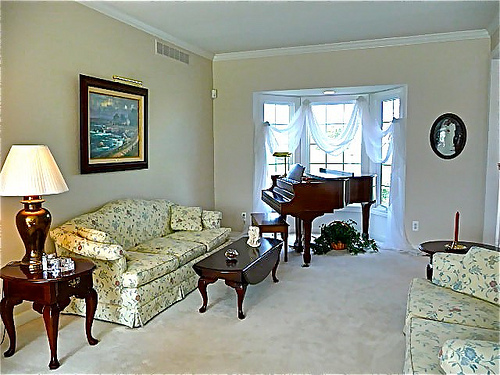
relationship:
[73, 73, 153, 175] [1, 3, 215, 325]
picture on wall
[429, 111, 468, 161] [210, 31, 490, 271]
picture on wall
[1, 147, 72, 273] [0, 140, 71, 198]
lamp has white shade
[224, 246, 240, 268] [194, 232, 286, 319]
candle on top of table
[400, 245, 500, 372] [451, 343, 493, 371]
couch has floral print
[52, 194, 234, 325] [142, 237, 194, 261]
couch has floral print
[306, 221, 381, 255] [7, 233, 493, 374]
plant on floor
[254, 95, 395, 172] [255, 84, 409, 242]
curtains on window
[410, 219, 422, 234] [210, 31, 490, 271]
electric plug on wall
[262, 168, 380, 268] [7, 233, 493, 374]
piano on floor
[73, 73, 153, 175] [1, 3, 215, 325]
painting on wall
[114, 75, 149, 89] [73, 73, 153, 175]
light above painting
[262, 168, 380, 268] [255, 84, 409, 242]
piano in front of window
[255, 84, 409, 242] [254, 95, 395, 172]
window has white curtains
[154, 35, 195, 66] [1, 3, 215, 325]
vent on wall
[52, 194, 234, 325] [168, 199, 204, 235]
couch has pillow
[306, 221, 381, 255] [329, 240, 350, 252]
plant in basket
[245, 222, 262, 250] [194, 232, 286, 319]
decoration on coffee table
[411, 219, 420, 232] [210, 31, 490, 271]
electric plug on wall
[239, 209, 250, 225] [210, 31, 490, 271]
outlet on wall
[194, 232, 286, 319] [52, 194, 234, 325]
coffee table in front of couch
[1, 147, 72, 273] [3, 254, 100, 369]
lamp on end table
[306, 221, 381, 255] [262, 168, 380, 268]
plant under piano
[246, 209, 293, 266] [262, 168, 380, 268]
bench in front of piano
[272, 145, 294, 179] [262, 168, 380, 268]
lamp on top of piano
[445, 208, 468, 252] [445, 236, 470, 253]
candle in candle holder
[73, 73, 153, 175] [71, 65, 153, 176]
painting has frame